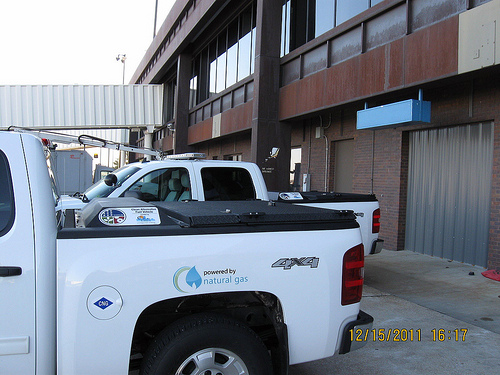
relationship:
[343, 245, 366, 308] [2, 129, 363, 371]
light on truck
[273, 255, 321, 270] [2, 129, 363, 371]
numbers on truck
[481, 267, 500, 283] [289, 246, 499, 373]
rag on ground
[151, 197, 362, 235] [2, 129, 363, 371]
cover on truck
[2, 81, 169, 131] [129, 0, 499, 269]
walkway attached to building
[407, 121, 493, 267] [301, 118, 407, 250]
door near wall